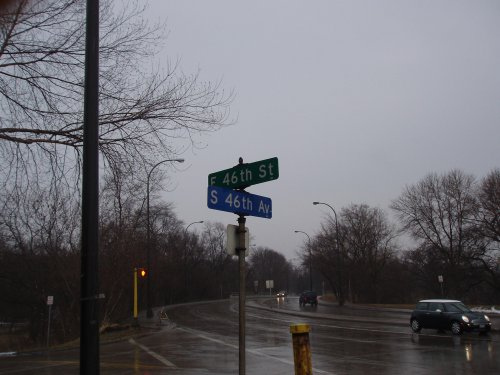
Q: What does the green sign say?
A: E 46th street.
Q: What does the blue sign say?
A: S 46th street.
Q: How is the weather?
A: Rainy.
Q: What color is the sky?
A: Gray.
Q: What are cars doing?
A: Driving.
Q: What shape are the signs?
A: Rectangular.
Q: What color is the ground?
A: Black.